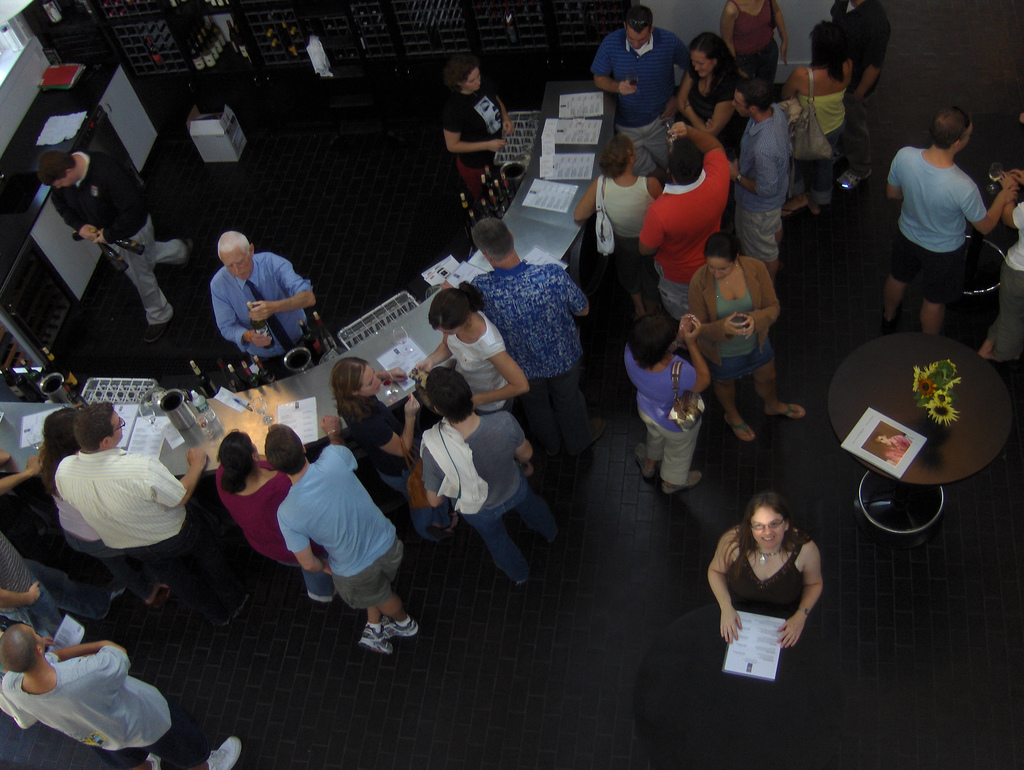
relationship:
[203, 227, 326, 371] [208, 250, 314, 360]
man in shirt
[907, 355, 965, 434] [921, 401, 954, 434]
sunflowers are in a vase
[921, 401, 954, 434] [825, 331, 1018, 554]
vase on table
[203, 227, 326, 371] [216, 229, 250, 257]
man has hair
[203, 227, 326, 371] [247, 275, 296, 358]
man wears a tie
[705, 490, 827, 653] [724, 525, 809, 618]
woman wears a tank top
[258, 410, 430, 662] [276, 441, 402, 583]
man wears top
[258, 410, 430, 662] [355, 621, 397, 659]
man wears sneaker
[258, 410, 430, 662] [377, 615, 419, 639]
man wears sneaker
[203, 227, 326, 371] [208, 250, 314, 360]
man wears shirt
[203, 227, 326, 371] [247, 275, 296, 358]
man wears tie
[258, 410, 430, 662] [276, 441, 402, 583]
man has top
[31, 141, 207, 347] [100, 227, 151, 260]
man carrying bottle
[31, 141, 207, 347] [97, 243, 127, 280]
man carrying bottle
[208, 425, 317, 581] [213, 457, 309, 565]
woman in a shirt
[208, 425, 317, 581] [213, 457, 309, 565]
woman wears a shirt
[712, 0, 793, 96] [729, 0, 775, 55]
woman in a shirt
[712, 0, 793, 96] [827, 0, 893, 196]
woman talking to a woman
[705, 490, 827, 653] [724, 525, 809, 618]
woman wearing tank top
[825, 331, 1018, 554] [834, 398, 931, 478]
table has book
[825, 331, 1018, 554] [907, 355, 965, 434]
table has sunflowers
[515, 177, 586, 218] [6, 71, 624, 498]
menu on bar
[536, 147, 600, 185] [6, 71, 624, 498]
menu on bar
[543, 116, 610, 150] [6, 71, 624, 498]
menu on bar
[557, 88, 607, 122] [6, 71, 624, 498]
menu on bar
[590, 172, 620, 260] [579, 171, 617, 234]
purse over woman's shoulder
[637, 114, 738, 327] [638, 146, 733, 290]
man in a shirt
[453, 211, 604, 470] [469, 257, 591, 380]
man in a shirt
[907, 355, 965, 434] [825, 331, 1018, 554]
sunflowers on a table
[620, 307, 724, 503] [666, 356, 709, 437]
woman has a purse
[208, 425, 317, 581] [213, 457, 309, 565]
woman has a shirt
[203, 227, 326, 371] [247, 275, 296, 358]
man has tie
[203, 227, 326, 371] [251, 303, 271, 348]
man opening bottle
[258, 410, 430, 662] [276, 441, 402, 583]
man wearing top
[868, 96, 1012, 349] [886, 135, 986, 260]
man has a shirt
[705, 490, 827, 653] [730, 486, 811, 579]
woman has hair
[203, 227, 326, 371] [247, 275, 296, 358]
man wearing tie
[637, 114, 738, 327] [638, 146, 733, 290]
man has shirt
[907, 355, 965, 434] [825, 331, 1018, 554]
sunflowers are on a table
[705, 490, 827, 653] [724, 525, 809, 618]
woman has tank top